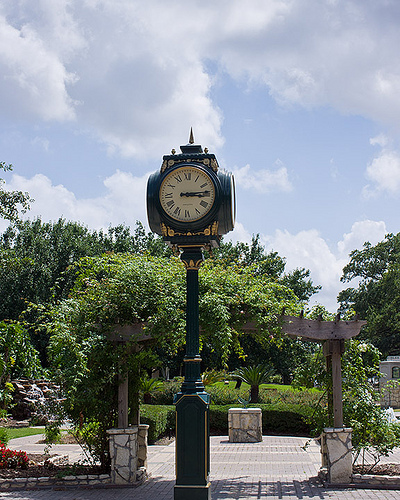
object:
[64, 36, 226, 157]
cloud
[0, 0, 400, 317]
sky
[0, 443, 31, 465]
flowers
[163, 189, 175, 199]
numerals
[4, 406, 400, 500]
walkway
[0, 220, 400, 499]
garden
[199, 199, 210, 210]
number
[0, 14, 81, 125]
clouds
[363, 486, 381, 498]
brick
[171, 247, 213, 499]
pole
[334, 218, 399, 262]
clouds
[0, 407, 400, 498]
floor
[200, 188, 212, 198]
number 3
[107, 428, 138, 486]
cobblestone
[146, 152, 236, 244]
cube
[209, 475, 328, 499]
shadow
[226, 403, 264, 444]
square block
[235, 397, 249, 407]
green sculpture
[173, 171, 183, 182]
number 11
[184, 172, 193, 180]
romannumeral 12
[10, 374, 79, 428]
fountain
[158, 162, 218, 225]
clock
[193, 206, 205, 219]
number 5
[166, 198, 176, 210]
roman numerals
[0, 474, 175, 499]
shadow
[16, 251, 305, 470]
plants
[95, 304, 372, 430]
wooden structure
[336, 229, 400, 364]
tree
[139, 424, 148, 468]
stone post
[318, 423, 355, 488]
stone post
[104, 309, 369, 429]
arbor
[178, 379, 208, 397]
trim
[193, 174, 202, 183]
roman numeral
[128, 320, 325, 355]
arch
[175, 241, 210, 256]
trim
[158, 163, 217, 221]
clockface